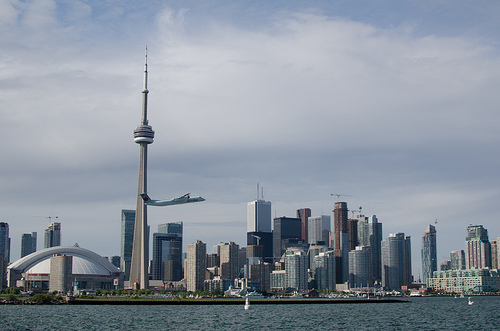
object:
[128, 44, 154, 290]
space needle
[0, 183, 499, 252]
skyline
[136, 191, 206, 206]
plane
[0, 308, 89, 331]
lake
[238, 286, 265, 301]
boats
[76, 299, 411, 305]
pier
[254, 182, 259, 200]
spire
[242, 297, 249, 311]
buoy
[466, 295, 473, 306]
buoy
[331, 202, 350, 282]
building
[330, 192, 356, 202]
crane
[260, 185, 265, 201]
spire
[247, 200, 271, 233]
building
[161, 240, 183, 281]
building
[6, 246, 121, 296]
building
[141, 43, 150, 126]
spire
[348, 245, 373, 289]
building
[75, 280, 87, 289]
window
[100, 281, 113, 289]
window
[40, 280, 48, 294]
window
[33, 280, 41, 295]
window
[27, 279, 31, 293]
window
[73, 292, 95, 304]
grass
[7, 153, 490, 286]
city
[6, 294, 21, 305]
bush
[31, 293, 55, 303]
bush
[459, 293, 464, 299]
boat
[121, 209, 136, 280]
building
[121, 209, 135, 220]
top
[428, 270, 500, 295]
building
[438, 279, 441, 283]
window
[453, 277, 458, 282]
window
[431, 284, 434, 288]
window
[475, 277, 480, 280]
window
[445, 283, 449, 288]
window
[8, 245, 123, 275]
roof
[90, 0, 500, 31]
blue sky